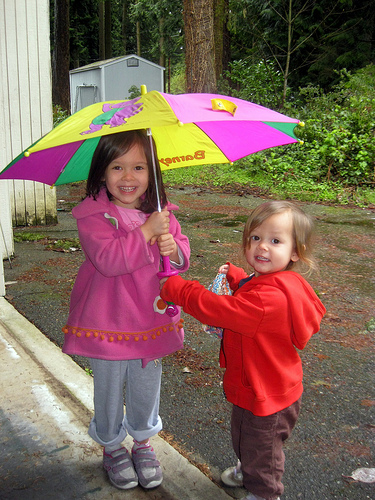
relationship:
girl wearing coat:
[34, 93, 204, 414] [54, 184, 195, 355]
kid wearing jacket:
[159, 198, 326, 500] [159, 260, 328, 416]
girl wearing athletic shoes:
[61, 128, 191, 491] [102, 444, 165, 487]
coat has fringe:
[66, 182, 197, 367] [61, 320, 187, 343]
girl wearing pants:
[61, 128, 191, 491] [86, 355, 163, 446]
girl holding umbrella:
[61, 128, 191, 491] [74, 78, 260, 187]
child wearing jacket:
[216, 213, 328, 409] [159, 261, 326, 416]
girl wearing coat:
[61, 128, 191, 491] [62, 184, 191, 367]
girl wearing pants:
[61, 128, 191, 491] [84, 342, 166, 454]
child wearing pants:
[158, 196, 327, 500] [220, 382, 305, 497]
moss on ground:
[311, 204, 373, 257] [0, 185, 375, 500]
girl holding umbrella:
[61, 128, 191, 491] [29, 79, 313, 206]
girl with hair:
[61, 128, 191, 491] [84, 128, 165, 212]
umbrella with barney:
[0, 85, 307, 186] [80, 95, 145, 135]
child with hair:
[158, 196, 327, 500] [239, 199, 318, 277]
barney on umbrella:
[83, 98, 147, 134] [4, 83, 339, 188]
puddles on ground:
[321, 220, 374, 289] [326, 368, 369, 473]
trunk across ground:
[181, 0, 221, 94] [0, 185, 375, 500]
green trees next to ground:
[309, 89, 372, 176] [0, 185, 375, 500]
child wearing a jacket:
[158, 196, 327, 500] [159, 261, 326, 416]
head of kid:
[232, 192, 318, 273] [164, 169, 361, 435]